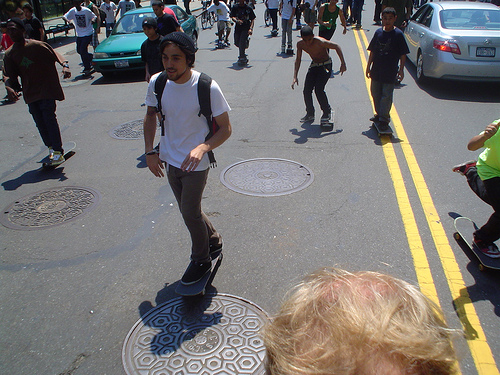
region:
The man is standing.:
[131, 27, 258, 329]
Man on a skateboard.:
[127, 30, 253, 311]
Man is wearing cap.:
[124, 27, 255, 326]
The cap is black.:
[118, 24, 247, 311]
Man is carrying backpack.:
[138, 21, 260, 323]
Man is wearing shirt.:
[123, 28, 248, 321]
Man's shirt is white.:
[116, 29, 251, 318]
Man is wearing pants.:
[133, 29, 241, 307]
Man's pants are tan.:
[139, 23, 244, 310]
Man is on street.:
[13, 19, 305, 374]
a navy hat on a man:
[160, 23, 198, 57]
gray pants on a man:
[153, 159, 223, 255]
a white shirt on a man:
[141, 68, 228, 174]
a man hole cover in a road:
[124, 286, 286, 372]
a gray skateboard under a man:
[170, 232, 228, 301]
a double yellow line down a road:
[348, 36, 497, 366]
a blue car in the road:
[81, 1, 198, 86]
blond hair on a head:
[246, 266, 469, 373]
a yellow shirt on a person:
[471, 109, 499, 181]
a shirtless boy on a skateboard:
[286, 23, 342, 139]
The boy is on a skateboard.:
[361, 4, 417, 162]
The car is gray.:
[403, 2, 498, 98]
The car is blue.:
[90, 4, 205, 79]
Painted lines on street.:
[336, 3, 499, 373]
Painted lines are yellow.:
[323, 0, 498, 372]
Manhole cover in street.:
[5, 234, 357, 374]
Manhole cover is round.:
[207, 144, 329, 213]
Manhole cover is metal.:
[1, 182, 111, 243]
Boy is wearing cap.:
[274, 23, 353, 140]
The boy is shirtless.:
[282, 25, 355, 137]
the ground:
[9, 175, 152, 324]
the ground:
[45, 205, 185, 358]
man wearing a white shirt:
[157, 102, 197, 172]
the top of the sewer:
[145, 309, 239, 374]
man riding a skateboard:
[313, 106, 348, 127]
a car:
[420, 12, 485, 72]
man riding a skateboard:
[29, 144, 92, 184]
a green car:
[97, 33, 137, 56]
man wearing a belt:
[306, 61, 329, 72]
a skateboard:
[446, 211, 497, 267]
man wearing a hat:
[296, 28, 313, 40]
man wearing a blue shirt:
[370, 29, 402, 79]